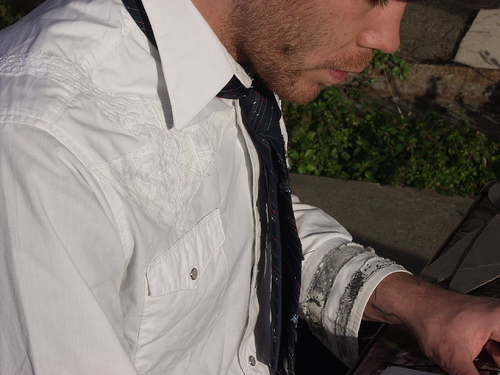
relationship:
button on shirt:
[188, 267, 199, 280] [42, 41, 301, 372]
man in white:
[2, 0, 416, 372] [2, 2, 416, 372]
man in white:
[0, 0, 499, 374] [2, 2, 416, 372]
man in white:
[0, 0, 499, 374] [2, 2, 498, 372]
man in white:
[0, 0, 499, 374] [53, 64, 198, 320]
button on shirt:
[188, 267, 199, 280] [6, 4, 418, 373]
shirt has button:
[6, 4, 418, 373] [182, 262, 202, 285]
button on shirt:
[188, 257, 210, 286] [14, 19, 310, 368]